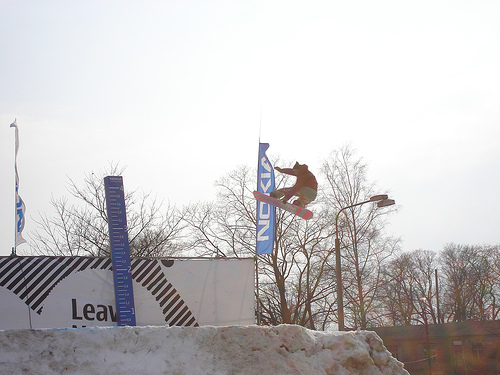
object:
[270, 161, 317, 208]
person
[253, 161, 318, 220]
tricks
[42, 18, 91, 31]
sky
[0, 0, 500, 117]
clouds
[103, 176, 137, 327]
device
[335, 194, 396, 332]
lighting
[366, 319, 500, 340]
awning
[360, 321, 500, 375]
building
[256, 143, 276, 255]
banner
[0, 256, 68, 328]
tarp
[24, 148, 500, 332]
trees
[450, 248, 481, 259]
leaves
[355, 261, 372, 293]
pole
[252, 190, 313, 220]
snowboard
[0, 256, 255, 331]
board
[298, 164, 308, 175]
cap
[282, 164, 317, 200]
jacket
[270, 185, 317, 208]
pants